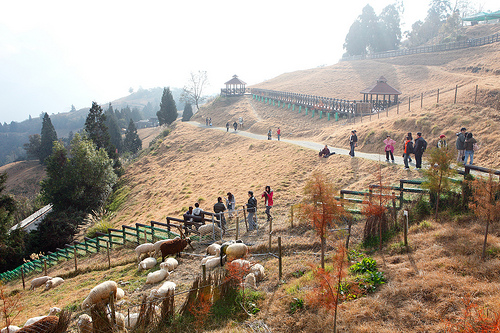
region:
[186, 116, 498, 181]
gray sidewalk along the hillside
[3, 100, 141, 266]
green trees on the hillside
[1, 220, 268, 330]
white sheep on the hillside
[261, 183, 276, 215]
woman with red jacket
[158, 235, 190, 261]
brown sheep on the hillside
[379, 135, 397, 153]
pink jacket on the person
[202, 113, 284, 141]
people on the sidewalk in the distance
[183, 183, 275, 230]
people looking at the animals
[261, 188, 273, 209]
Woman is wearing a jacket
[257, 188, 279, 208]
Woman wearing a red jacket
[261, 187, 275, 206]
Woman is wearing a red jacket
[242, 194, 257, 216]
Man wearing a jacket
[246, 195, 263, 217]
Man is wearing a jacket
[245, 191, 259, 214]
Man is wearing a black jacket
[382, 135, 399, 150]
Woman is wearing a shirt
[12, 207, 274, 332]
the sheep are fenced in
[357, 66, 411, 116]
this is a gazebo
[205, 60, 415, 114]
there are two gazebos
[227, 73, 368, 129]
a raised walkway that connects the gazebos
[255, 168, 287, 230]
she is wearing a red jacket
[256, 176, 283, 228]
she is taking a picture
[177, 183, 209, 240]
they are leaning on the fence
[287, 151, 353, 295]
the tree has orange leaves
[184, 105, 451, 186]
people are walking on this narrow road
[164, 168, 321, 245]
a group of people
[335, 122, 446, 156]
another group of people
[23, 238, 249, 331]
a group of sheeps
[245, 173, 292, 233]
a girl standing in the back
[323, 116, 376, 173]
a man walking in road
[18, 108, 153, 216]
a large group of trees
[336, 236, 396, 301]
a green grass near sheeps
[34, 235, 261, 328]
sheeps eating their food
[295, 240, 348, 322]
red trees in between sheeps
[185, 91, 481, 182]
people standing on sidewalk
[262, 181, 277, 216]
person in red shirt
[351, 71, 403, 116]
this is a open hut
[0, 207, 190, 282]
green trim on stairs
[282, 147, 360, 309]
sparse leafs on the tree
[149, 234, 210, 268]
this is a brown sheep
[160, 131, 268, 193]
hillside grass is yellow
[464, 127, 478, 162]
a person is standing up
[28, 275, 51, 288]
a sheep in a field of grass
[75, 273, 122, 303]
a sheep in a field of grass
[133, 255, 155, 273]
a sheep in a field of grass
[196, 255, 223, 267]
a sheep in a field of grass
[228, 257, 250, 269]
a sheep in a field of grass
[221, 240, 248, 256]
a sheep in a field of grass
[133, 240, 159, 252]
a sheep in a field of grass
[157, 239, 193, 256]
a sheep in a field of grass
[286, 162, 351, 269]
red and yellow leaves on tree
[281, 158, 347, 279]
red and yellow leaves on tree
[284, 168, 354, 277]
red and yellow leaves on tree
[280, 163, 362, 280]
red and yellow leaves on tree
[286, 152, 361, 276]
red and yellow leaves on tree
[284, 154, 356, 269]
red and yellow leaves on tree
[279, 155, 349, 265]
red and yellow leaves on tree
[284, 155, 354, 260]
red and yellow leaves on tree